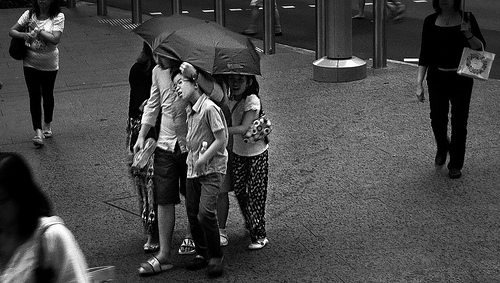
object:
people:
[226, 74, 272, 250]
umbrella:
[130, 15, 260, 75]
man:
[133, 53, 222, 252]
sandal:
[137, 255, 176, 275]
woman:
[415, 0, 487, 178]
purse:
[9, 9, 32, 59]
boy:
[171, 73, 230, 277]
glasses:
[172, 78, 189, 89]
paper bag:
[456, 42, 495, 81]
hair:
[26, 0, 70, 19]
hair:
[432, 0, 463, 16]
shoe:
[31, 134, 43, 145]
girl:
[10, 0, 65, 145]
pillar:
[311, 0, 367, 83]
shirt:
[418, 10, 488, 69]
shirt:
[17, 10, 64, 70]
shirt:
[232, 94, 269, 157]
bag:
[242, 109, 272, 144]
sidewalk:
[4, 9, 493, 280]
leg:
[448, 85, 472, 170]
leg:
[195, 175, 224, 259]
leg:
[154, 155, 180, 256]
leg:
[245, 153, 267, 238]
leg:
[25, 75, 42, 135]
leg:
[129, 148, 154, 241]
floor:
[7, 37, 398, 187]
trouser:
[154, 142, 183, 203]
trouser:
[41, 70, 58, 123]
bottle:
[130, 137, 157, 175]